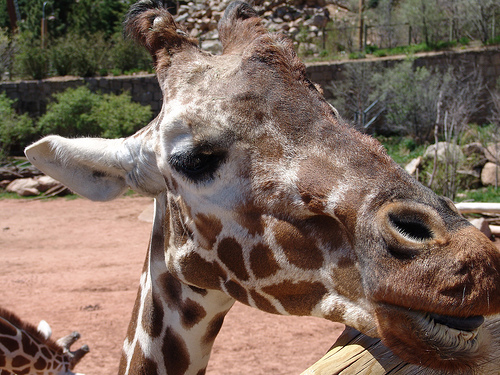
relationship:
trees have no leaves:
[319, 38, 484, 141] [421, 45, 482, 128]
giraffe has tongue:
[23, 0, 498, 374] [402, 318, 487, 350]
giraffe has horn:
[23, 0, 498, 374] [124, 0, 215, 90]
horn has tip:
[124, 0, 215, 90] [137, 7, 167, 32]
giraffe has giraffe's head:
[23, 0, 498, 374] [24, 4, 499, 370]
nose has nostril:
[361, 175, 497, 265] [380, 201, 465, 263]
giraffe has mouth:
[23, 0, 498, 374] [373, 249, 498, 364]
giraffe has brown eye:
[23, 0, 498, 374] [165, 140, 229, 190]